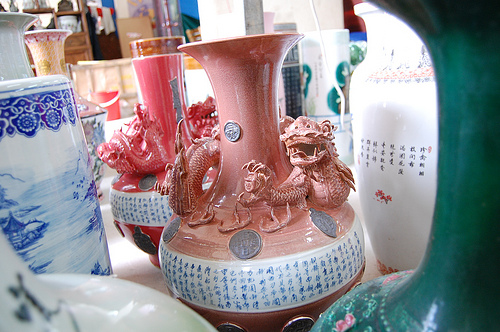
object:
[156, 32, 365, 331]
ceramic vase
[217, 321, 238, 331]
coin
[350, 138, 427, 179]
writing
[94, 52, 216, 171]
neck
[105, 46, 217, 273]
vase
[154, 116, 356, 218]
dragon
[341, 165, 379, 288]
ground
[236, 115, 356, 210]
dragon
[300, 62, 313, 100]
green flower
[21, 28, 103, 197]
white vase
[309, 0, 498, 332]
vase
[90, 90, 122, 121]
bucket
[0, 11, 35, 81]
vase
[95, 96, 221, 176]
dragon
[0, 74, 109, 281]
vase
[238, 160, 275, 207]
statue`s part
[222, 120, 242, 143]
coin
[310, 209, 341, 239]
coin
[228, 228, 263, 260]
coin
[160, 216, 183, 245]
coin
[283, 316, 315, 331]
coin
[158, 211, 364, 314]
lettering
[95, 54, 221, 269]
red vase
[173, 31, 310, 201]
neck